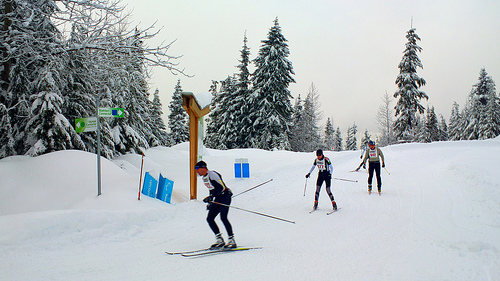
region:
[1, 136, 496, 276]
Snow is covering the ground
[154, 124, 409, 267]
Three skiers in the image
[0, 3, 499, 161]
Trees are snow covered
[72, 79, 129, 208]
Two direction signs in the background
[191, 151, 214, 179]
Man is wearing a black cap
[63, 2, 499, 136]
The sky is light gray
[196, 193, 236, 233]
Man is wearing dark blue pants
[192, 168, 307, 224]
Man is holding ski poles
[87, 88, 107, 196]
Pole is silver in color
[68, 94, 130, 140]
The directional signs are green in color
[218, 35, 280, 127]
trees covered in snow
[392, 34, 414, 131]
trees covered in snow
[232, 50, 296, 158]
trees covered in snow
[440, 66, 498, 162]
trees covered in snow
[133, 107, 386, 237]
the people are skiing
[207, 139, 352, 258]
the people are skiing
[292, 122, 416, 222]
the people are skiing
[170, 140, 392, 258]
Three people skiing in snow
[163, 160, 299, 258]
Man skiing in snow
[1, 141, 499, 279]
Ground covered with snow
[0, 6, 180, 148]
Trees covered with snow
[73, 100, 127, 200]
Signs on a pole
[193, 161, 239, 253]
Man in black and white outfit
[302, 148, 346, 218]
Man wearing skiing gear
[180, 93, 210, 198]
Tall wooden mail box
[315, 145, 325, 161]
Man wearing black cap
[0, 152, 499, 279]
White snow on ground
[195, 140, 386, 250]
the people on the snow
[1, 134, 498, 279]
the snow on the ground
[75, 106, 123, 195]
the pole with two signs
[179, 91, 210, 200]
the wooden structure sticking out of the snow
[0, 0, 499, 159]
the trees with snow on them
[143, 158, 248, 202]
the blue objects sticking out from the snow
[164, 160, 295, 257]
the man skiing on the snow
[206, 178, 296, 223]
the ski poles in the man's hands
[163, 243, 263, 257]
the skis under the man's feet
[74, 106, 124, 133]
the green and white signs on the pole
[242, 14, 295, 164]
a snow covered pine tree.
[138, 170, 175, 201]
flags sticking in the snow.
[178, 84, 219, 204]
a metal pole on a ski slope.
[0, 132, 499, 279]
a snow covered ski slope.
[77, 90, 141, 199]
a road sign on a snow covered slope.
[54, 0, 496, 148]
a hazy gray sky.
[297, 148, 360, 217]
a man on a ski slope.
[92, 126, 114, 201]
a pole on a snow slope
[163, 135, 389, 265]
people in a ski race.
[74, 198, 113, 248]
a patch of white snow.